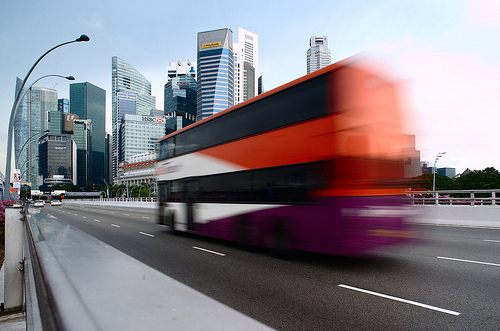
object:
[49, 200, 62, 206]
car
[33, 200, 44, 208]
car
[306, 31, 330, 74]
building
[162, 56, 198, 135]
building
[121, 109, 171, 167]
building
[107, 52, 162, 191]
building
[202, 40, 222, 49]
sign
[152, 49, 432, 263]
bus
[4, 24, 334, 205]
city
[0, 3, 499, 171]
sky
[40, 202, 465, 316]
lines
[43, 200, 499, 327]
lanes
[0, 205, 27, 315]
white pillar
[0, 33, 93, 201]
curved lampposts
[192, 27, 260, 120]
angled building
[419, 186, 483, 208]
partition/railing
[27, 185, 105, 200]
overpass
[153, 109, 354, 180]
white/red stripe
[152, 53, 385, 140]
bus top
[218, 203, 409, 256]
bus trim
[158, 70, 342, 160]
top windows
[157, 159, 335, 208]
bottom row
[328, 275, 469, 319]
white line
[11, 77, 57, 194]
skyscrapers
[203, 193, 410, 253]
lower bus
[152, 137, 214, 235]
bus front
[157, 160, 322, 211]
lower windows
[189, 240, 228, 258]
white line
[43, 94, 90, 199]
sky scraper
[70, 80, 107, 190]
sky scraper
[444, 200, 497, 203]
rails